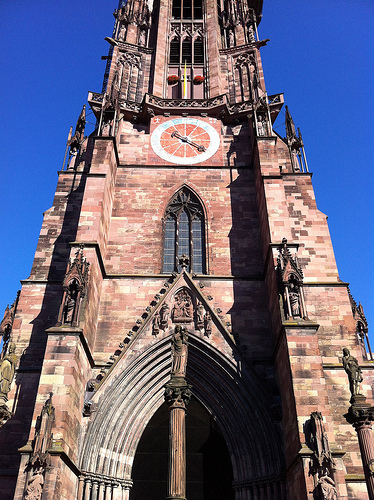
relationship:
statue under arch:
[168, 321, 190, 390] [78, 327, 286, 498]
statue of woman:
[168, 321, 190, 390] [171, 323, 190, 378]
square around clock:
[149, 112, 230, 167] [150, 117, 219, 163]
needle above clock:
[177, 56, 189, 101] [148, 108, 221, 167]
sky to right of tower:
[253, 0, 373, 352] [0, 5, 373, 489]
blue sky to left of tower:
[1, 1, 119, 353] [0, 5, 373, 489]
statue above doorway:
[170, 324, 189, 384] [127, 390, 237, 494]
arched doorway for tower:
[130, 392, 234, 499] [0, 5, 373, 489]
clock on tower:
[148, 116, 222, 169] [0, 5, 373, 489]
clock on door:
[148, 116, 222, 169] [80, 332, 245, 498]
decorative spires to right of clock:
[281, 103, 307, 172] [148, 116, 222, 169]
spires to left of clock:
[60, 104, 86, 172] [150, 117, 219, 163]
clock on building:
[147, 114, 224, 169] [23, 6, 361, 497]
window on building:
[157, 179, 218, 276] [115, 19, 277, 276]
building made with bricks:
[23, 6, 361, 497] [116, 165, 153, 253]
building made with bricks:
[23, 6, 361, 497] [203, 169, 260, 250]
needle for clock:
[168, 129, 210, 154] [123, 92, 235, 178]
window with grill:
[180, 28, 191, 67] [181, 35, 191, 61]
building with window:
[23, 6, 361, 497] [153, 175, 218, 277]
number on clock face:
[180, 152, 194, 164] [151, 116, 226, 164]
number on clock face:
[171, 117, 182, 124] [151, 116, 226, 164]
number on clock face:
[157, 121, 170, 129] [151, 116, 226, 164]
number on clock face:
[180, 114, 196, 126] [151, 116, 226, 164]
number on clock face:
[202, 125, 208, 130] [151, 116, 226, 164]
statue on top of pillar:
[329, 330, 363, 402] [10, 17, 292, 206]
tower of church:
[171, 0, 208, 69] [10, 4, 364, 482]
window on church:
[161, 183, 207, 276] [62, 8, 307, 499]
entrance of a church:
[120, 386, 234, 498] [10, 4, 364, 482]